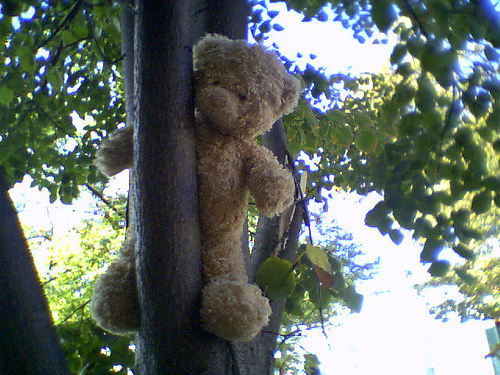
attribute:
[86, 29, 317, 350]
teddy bear — brown, fuzzy, fluffy, watching, cute, creepy, stuck, light brown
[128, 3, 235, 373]
tree branch — brown, long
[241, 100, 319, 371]
tree branch — broken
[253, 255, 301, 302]
leaf — green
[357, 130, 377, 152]
leaf — green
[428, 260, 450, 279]
leaf — green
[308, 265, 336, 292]
leaf — brown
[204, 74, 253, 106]
eyes — black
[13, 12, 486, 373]
sky — bright, clear